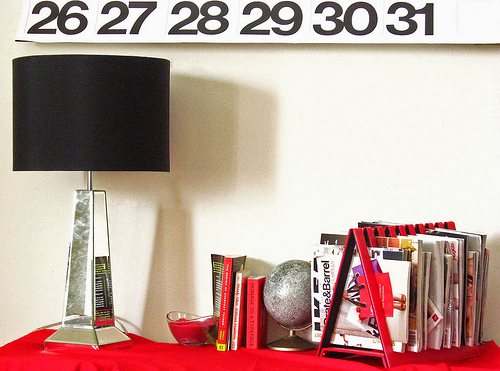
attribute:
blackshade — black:
[9, 49, 176, 178]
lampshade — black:
[13, 54, 170, 174]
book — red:
[245, 272, 267, 350]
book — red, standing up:
[208, 253, 245, 350]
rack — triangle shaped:
[307, 202, 496, 364]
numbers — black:
[221, 0, 429, 42]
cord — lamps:
[40, 321, 60, 331]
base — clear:
[53, 177, 128, 366]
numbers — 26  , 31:
[25, 0, 445, 37]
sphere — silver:
[264, 258, 313, 323]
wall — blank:
[306, 159, 429, 209]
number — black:
[306, 9, 376, 32]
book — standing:
[245, 268, 271, 348]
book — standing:
[227, 267, 245, 352]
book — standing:
[211, 247, 248, 351]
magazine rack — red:
[311, 217, 482, 368]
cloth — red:
[146, 347, 176, 367]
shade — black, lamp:
[9, 54, 172, 173]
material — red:
[3, 327, 498, 369]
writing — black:
[316, 262, 334, 321]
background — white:
[18, 1, 452, 38]